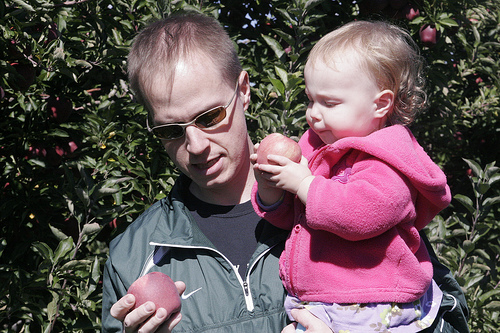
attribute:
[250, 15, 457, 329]
baby — blonde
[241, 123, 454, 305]
jacket — pink, small, fuzzy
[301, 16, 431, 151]
blond hair — curly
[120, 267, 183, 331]
apple — large, red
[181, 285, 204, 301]
logo — nike , white , swoosh 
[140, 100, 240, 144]
glasses — dark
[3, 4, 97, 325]
tree — apple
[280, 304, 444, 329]
shirt — purple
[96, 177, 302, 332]
breaker — grey, dark green